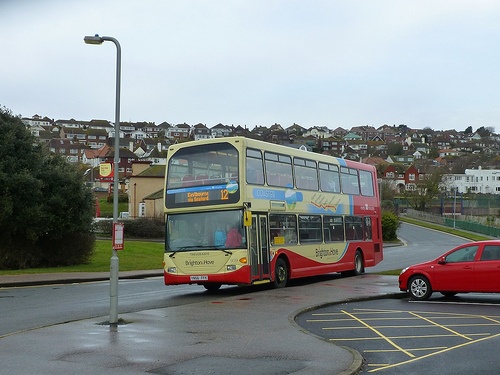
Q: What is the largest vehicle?
A: The bus.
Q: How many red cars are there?
A: One.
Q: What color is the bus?
A: Yellow and red.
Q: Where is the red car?
A: In a parking lot.